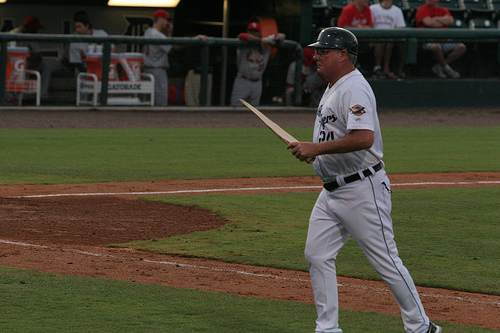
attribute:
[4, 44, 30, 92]
container — orange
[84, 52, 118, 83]
container — orange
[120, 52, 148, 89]
container — orange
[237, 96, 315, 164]
wood — broken bat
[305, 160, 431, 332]
pants — white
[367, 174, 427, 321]
stripe — black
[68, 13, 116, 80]
player — talking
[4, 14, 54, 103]
player — talking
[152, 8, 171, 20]
cap — red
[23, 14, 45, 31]
cap — red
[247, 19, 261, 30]
cap — red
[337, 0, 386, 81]
person — watching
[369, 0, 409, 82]
person — watching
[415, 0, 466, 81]
person — watching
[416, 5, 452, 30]
shirt — red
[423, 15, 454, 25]
arms — crossed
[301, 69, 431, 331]
uniform — white, black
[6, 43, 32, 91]
drink cooler — orange, grey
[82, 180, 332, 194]
strip — white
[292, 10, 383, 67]
helmet — black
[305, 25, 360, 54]
helmet — black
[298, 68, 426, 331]
costume — white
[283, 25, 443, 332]
man — walking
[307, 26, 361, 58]
helmet — black, dark blue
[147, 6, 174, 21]
hat — red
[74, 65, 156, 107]
trolley — white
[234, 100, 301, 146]
stake — wooden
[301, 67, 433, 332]
dress — white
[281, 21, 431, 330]
baseball player — leaning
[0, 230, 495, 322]
lines — white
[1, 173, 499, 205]
lines — white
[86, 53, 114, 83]
cooler — orange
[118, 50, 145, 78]
cooler — orange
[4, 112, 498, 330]
grass — green, soil